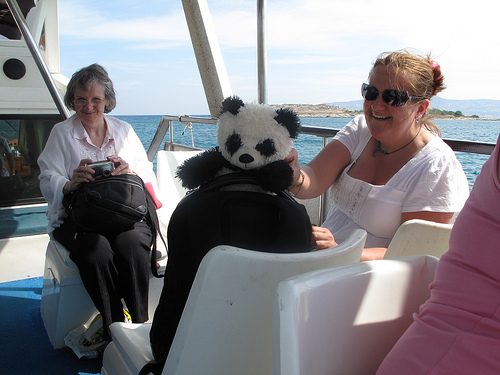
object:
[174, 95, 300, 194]
stuffed animal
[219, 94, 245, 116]
black ears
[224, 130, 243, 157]
eyes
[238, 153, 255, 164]
nose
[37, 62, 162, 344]
woman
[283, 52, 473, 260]
woman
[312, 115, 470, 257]
white top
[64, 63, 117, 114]
hair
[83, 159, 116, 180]
camera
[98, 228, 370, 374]
chair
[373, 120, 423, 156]
necklace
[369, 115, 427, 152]
neck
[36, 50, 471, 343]
two women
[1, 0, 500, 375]
boat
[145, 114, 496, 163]
rail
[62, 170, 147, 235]
bag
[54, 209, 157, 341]
pants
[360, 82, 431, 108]
sunglasses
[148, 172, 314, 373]
luggage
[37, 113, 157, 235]
white shirt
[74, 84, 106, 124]
face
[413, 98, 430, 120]
ear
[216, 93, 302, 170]
head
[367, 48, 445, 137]
hair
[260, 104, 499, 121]
mountain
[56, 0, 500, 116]
sky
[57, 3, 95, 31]
clouds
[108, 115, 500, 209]
body of water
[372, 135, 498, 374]
shirt